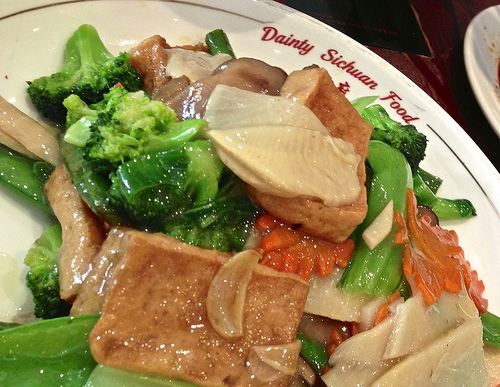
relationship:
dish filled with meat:
[4, 1, 500, 367] [9, 21, 461, 381]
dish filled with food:
[4, 1, 500, 367] [0, 25, 499, 386]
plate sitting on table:
[450, 15, 499, 107] [340, 5, 491, 144]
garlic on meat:
[202, 247, 260, 339] [93, 226, 308, 376]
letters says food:
[259, 22, 421, 124] [378, 85, 415, 127]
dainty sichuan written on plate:
[261, 20, 381, 96] [3, 4, 485, 280]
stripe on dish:
[1, 3, 496, 234] [4, 1, 500, 367]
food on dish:
[0, 25, 499, 386] [4, 1, 500, 367]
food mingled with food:
[0, 25, 499, 386] [456, 338, 461, 342]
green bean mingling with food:
[371, 148, 406, 204] [253, 130, 418, 298]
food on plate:
[21, 47, 428, 361] [251, 20, 498, 187]